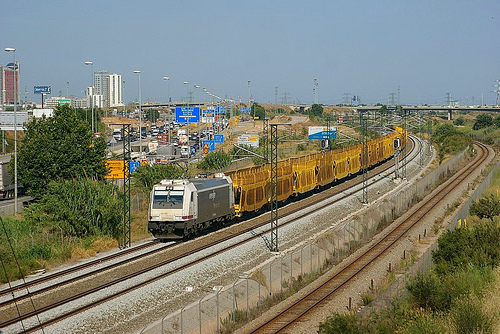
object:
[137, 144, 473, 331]
fence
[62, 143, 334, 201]
fence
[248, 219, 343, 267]
gravel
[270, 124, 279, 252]
metal tower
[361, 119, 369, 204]
metal tower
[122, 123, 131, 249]
metal tower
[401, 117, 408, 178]
metal tower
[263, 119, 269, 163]
metal tower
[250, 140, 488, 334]
train tracks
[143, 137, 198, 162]
traffic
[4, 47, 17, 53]
street light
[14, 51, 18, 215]
pole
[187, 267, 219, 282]
rocks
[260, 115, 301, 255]
tower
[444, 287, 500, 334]
bush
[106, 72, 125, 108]
building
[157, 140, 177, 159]
truck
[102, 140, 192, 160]
road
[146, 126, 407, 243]
train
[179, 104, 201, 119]
sign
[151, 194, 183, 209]
window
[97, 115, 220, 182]
road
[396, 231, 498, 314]
tree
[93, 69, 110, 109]
building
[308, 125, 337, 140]
billboard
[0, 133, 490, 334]
track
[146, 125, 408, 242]
towed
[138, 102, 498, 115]
overpass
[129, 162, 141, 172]
lettering